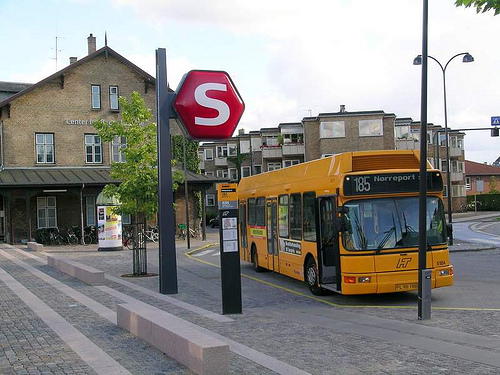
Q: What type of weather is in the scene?
A: It is overcast.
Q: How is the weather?
A: It is overcast.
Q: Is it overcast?
A: Yes, it is overcast.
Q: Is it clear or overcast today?
A: It is overcast.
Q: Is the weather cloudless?
A: No, it is overcast.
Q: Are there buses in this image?
A: Yes, there is a bus.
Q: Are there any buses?
A: Yes, there is a bus.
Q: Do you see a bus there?
A: Yes, there is a bus.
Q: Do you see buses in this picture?
A: Yes, there is a bus.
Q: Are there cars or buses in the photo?
A: Yes, there is a bus.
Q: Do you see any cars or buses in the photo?
A: Yes, there is a bus.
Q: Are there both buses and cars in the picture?
A: No, there is a bus but no cars.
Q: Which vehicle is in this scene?
A: The vehicle is a bus.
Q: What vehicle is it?
A: The vehicle is a bus.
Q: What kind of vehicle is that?
A: This is a bus.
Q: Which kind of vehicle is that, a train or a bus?
A: This is a bus.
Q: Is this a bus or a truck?
A: This is a bus.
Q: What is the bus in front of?
A: The bus is in front of the door.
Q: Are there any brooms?
A: No, there are no brooms.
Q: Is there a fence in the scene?
A: No, there are no fences.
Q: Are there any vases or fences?
A: No, there are no fences or vases.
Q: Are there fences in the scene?
A: No, there are no fences.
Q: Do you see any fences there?
A: No, there are no fences.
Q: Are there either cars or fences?
A: No, there are no fences or cars.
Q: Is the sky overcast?
A: Yes, the sky is overcast.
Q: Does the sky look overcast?
A: Yes, the sky is overcast.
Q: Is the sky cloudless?
A: No, the sky is overcast.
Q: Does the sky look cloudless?
A: No, the sky is overcast.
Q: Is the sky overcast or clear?
A: The sky is overcast.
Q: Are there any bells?
A: No, there are no bells.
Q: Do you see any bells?
A: No, there are no bells.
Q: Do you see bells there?
A: No, there are no bells.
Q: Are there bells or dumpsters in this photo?
A: No, there are no bells or dumpsters.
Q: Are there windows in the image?
A: Yes, there is a window.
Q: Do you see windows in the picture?
A: Yes, there is a window.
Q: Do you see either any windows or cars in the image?
A: Yes, there is a window.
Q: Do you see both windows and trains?
A: No, there is a window but no trains.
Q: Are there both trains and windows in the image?
A: No, there is a window but no trains.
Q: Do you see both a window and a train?
A: No, there is a window but no trains.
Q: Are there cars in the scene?
A: No, there are no cars.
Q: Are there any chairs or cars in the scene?
A: No, there are no cars or chairs.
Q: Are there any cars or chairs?
A: No, there are no cars or chairs.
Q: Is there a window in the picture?
A: Yes, there is a window.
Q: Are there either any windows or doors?
A: Yes, there is a window.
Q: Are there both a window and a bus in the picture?
A: Yes, there are both a window and a bus.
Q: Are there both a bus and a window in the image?
A: Yes, there are both a window and a bus.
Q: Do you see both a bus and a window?
A: Yes, there are both a window and a bus.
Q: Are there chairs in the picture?
A: No, there are no chairs.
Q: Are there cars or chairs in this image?
A: No, there are no chairs or cars.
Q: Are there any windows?
A: Yes, there is a window.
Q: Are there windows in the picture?
A: Yes, there is a window.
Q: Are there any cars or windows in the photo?
A: Yes, there is a window.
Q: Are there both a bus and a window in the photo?
A: Yes, there are both a window and a bus.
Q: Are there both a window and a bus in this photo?
A: Yes, there are both a window and a bus.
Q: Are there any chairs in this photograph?
A: No, there are no chairs.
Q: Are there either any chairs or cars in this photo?
A: No, there are no chairs or cars.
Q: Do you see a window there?
A: Yes, there are windows.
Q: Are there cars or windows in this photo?
A: Yes, there are windows.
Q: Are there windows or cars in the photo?
A: Yes, there are windows.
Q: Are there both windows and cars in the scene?
A: No, there are windows but no cars.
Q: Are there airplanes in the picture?
A: No, there are no airplanes.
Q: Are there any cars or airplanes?
A: No, there are no airplanes or cars.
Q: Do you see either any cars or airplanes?
A: No, there are no airplanes or cars.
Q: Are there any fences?
A: No, there are no fences.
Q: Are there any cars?
A: No, there are no cars.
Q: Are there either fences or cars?
A: No, there are no cars or fences.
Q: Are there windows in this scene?
A: Yes, there is a window.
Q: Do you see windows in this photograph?
A: Yes, there is a window.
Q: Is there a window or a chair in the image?
A: Yes, there is a window.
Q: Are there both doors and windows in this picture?
A: Yes, there are both a window and a door.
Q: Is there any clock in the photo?
A: No, there are no clocks.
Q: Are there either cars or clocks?
A: No, there are no clocks or cars.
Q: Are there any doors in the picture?
A: Yes, there is a door.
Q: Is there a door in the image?
A: Yes, there is a door.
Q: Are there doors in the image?
A: Yes, there is a door.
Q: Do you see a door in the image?
A: Yes, there is a door.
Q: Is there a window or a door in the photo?
A: Yes, there is a door.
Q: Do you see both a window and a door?
A: Yes, there are both a door and a window.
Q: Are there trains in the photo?
A: No, there are no trains.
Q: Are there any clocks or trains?
A: No, there are no trains or clocks.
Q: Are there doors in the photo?
A: Yes, there is a door.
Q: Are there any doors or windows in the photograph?
A: Yes, there is a door.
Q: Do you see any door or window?
A: Yes, there is a door.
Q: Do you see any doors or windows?
A: Yes, there is a door.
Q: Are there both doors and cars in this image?
A: No, there is a door but no cars.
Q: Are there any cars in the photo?
A: No, there are no cars.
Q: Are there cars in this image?
A: No, there are no cars.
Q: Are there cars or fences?
A: No, there are no cars or fences.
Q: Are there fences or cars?
A: No, there are no cars or fences.